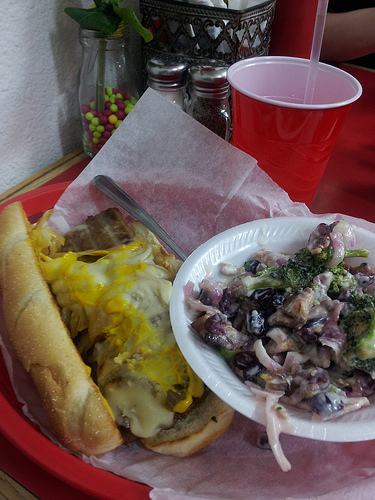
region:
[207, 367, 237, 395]
a paper bowl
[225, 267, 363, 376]
food in the bowl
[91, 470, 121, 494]
the rim of the plate is red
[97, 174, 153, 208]
the handle of a utensil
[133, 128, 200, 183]
white tissue paper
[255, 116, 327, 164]
a red cup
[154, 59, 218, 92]
salt and pepper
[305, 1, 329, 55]
a straw in the cup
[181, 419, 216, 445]
the bun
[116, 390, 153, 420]
white cheese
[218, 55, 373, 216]
Red cup on the table.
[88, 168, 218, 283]
Utensil on the plate.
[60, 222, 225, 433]
Mustard on the hot dog.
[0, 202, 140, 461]
Bun on the hot dog.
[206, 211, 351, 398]
Salad in the bowl.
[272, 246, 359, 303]
Broccoli in the bowl.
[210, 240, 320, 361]
Raisins in the bowl.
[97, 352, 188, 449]
Cheese on the hot dog.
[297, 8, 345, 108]
Straw in the cup.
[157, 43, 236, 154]
Salt and pepper shakers.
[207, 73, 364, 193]
Red Solo cup on the table.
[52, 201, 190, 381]
Sausage sandwich on a roll.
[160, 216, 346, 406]
White foam plate holding food.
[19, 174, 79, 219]
Red plastic container holding the food.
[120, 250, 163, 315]
Cheese on the sausage sandwich.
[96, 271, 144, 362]
Yellow mustard on the sandwich.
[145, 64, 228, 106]
Salt and pepper on the table.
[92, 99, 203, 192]
Wax paper lining the basket.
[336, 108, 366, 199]
Red table holding the food.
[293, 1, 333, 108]
Clear straw in the cup.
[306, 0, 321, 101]
The straw in the red cup.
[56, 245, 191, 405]
The mustard on the sandwich.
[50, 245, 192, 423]
The melted cheese on the sandwich.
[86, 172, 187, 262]
The handle of the utensil under the white foam plate.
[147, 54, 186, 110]
The salt shaker behind the sandwich.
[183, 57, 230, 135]
The pepper shaker next to the red cup.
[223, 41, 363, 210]
The red cup on the table.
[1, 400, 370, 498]
The red tray/plate the food is located on.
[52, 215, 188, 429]
The meat on the sandwich.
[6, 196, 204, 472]
The toasted bread of the sandwich.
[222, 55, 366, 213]
Red plastic cup on table.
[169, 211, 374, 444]
Broccoli salad in a bowl.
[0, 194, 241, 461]
Sandwich on a plate.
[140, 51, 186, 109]
Salt shaker in the background.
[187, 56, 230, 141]
Black pepper shaker in the background.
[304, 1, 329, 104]
Clear straw in the drink.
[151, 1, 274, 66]
Napkin holder in the background.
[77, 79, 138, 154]
Green, yellow, and red objects in glass vase.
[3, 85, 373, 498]
White paper wrapper under food.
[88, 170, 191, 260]
Silver eating utensil on plate.